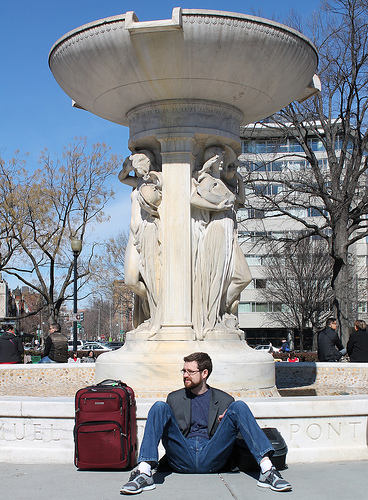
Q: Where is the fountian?
A: Behind the man.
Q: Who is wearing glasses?
A: The man.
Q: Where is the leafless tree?
A: In front of the building.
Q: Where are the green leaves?
A: On the tree.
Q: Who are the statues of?
A: Two women.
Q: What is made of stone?
A: The fountain.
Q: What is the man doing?
A: Sitting by a fountain.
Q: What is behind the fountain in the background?
A: A building with lots of windows.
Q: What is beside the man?
A: A red suitcase.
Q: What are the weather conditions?
A: Clear and sunny.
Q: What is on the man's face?
A: Glasses.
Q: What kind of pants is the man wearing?
A: Blue jeans.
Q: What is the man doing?
A: Sitting on the ground.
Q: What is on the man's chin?
A: Facial hair.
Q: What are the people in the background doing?
A: Talking.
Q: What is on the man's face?
A: The man has a brown beard.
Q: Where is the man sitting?
A: A man sitting on ground.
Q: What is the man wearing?
A: A pair of blue jeans.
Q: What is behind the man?
A: A sculptural water fountain.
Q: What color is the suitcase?
A: Red.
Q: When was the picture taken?
A: Daytime.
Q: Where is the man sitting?
A: The ground.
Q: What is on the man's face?
A: Glasses.